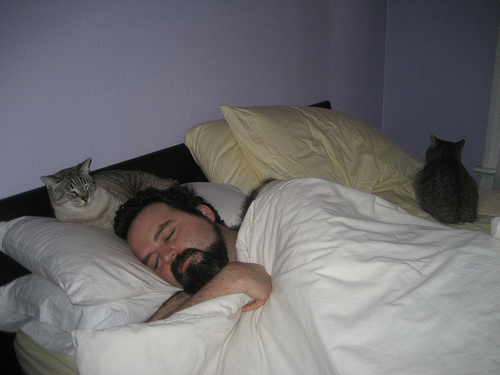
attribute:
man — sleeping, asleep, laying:
[112, 174, 500, 371]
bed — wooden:
[3, 98, 496, 370]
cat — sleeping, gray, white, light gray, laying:
[43, 161, 179, 232]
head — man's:
[112, 174, 227, 300]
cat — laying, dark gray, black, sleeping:
[413, 132, 482, 227]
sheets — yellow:
[183, 97, 498, 220]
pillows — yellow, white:
[181, 95, 439, 215]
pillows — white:
[3, 177, 261, 328]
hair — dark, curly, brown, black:
[111, 185, 228, 241]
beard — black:
[169, 223, 228, 298]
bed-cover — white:
[55, 175, 499, 367]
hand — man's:
[213, 254, 276, 310]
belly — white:
[84, 202, 112, 221]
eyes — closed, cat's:
[67, 182, 96, 199]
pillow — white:
[9, 181, 245, 310]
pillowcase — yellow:
[221, 96, 435, 208]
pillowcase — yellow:
[184, 115, 265, 203]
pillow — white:
[1, 280, 163, 352]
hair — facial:
[167, 223, 230, 301]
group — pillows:
[4, 174, 261, 352]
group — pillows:
[184, 96, 426, 214]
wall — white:
[5, 0, 500, 200]